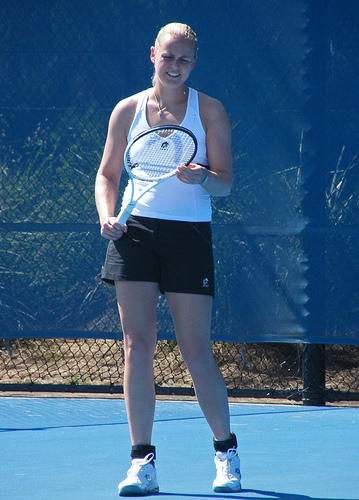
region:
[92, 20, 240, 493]
Young lady getting ready to play tennis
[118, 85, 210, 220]
White tank top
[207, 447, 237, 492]
Left tennis shoe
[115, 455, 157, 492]
Right tennis shoe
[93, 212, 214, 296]
Black shorts worn by tennis player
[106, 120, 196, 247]
Tennis rack in right hand of tennis player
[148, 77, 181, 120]
Necklace around young lady's neck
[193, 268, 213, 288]
Logo on black shorts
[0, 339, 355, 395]
Fence in back of tennis player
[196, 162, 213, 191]
Watch on left wrist of tennis player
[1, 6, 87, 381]
Chain link fence with netting on it.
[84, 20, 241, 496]
a Female Tennis player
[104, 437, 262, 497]
A Pair of White Tennis Shoes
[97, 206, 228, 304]
A Pair of Black Tennis Shorts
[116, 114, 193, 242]
A White and Black Tennis Racket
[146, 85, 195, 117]
Some sort of necklace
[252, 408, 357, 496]
Green Space on the Tennis Court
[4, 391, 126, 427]
Shadow on the Tennis Court from the Chain Link Fence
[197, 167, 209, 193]
Some Sort of Tennis Bracelet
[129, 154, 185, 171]
Some Damaged Strings in the tennis Racket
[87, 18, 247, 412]
woman holding tennis racket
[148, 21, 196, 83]
woman with blonde hair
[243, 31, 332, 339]
blue screen draped over fence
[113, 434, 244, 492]
pair of white sneakers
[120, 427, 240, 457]
black ankle weights strapped to legs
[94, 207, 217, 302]
black shorts with white logo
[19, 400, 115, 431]
shadow of fence on court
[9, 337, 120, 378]
bottom of chain link fence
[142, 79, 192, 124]
gold necklace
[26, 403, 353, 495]
blue tennis court floor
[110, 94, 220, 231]
woman's shirt is white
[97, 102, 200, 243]
woman holding a tennis racket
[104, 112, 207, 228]
tennis racket is white and black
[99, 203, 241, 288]
woman's shorts are black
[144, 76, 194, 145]
woman wearing a necklace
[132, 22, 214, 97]
woman looking at racket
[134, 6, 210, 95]
woman's hair is blonde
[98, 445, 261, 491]
woman's shoes are white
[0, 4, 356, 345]
the material on fence is blue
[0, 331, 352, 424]
fence is made of metal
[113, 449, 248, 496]
sneakers on tennis court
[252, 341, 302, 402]
bottom of chain link fence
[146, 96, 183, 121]
jewelry on woman's neck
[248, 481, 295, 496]
shadow of woman on court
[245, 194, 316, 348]
blue fabric on fence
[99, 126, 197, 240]
racket in woman's hand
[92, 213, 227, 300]
black shorts on woman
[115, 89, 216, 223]
tank top on player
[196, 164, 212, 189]
bracelet on woman's wrist